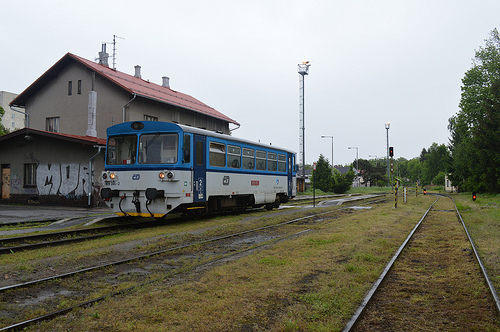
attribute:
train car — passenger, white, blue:
[119, 119, 293, 213]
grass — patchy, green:
[223, 239, 338, 308]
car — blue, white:
[110, 122, 303, 202]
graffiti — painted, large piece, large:
[34, 167, 94, 207]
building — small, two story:
[7, 71, 190, 202]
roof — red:
[23, 50, 231, 114]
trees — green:
[374, 63, 490, 184]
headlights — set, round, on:
[101, 167, 183, 182]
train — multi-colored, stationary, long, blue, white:
[100, 120, 301, 204]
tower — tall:
[291, 49, 322, 196]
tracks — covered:
[80, 227, 381, 321]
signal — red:
[471, 188, 480, 207]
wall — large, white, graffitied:
[12, 141, 101, 205]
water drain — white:
[86, 154, 97, 207]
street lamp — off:
[378, 117, 393, 132]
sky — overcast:
[8, 6, 486, 167]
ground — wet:
[45, 158, 487, 332]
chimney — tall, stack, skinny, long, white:
[88, 85, 101, 137]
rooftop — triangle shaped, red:
[66, 51, 237, 133]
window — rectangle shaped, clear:
[139, 131, 182, 160]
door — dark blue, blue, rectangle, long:
[193, 135, 206, 205]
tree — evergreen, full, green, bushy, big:
[442, 24, 493, 189]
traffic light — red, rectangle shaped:
[386, 141, 394, 165]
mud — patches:
[76, 243, 156, 287]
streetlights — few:
[320, 119, 419, 180]